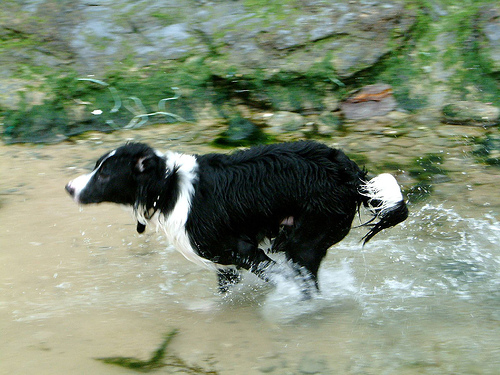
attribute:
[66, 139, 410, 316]
dog — black, white, running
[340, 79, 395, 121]
rock — gray